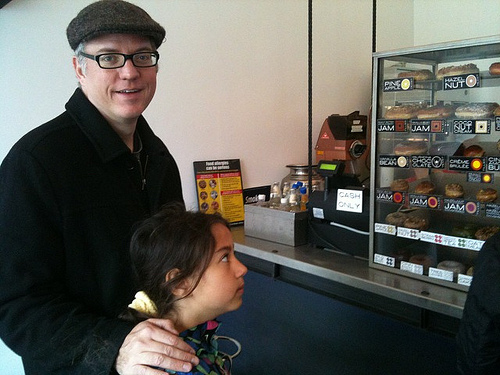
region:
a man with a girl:
[2, 2, 199, 373]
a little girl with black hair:
[120, 210, 247, 373]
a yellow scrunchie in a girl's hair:
[125, 285, 160, 318]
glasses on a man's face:
[80, 45, 160, 70]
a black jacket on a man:
[0, 85, 182, 371]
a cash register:
[307, 155, 368, 255]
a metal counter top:
[205, 215, 495, 365]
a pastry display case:
[362, 30, 492, 280]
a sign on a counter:
[187, 155, 253, 226]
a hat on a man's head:
[63, 1, 169, 46]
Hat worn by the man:
[63, 0, 170, 50]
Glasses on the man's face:
[75, 45, 162, 72]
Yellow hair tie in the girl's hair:
[122, 286, 158, 320]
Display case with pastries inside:
[361, 23, 498, 293]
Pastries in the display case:
[384, 58, 498, 283]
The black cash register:
[301, 148, 373, 265]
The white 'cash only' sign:
[332, 182, 367, 216]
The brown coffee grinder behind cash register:
[309, 106, 368, 173]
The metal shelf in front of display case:
[228, 220, 469, 317]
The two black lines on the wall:
[302, 0, 381, 199]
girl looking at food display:
[120, 210, 282, 374]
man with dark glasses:
[65, 0, 166, 125]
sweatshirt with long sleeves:
[0, 84, 220, 373]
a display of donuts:
[364, 35, 497, 305]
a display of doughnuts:
[354, 39, 498, 299]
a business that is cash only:
[329, 184, 366, 216]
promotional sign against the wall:
[190, 150, 251, 239]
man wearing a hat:
[55, 0, 177, 128]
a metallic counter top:
[281, 237, 478, 312]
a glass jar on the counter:
[273, 155, 329, 212]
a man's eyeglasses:
[73, 48, 160, 68]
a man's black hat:
[59, 0, 169, 47]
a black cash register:
[307, 158, 374, 256]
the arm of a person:
[452, 227, 498, 374]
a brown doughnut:
[442, 179, 463, 199]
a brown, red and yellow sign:
[192, 159, 246, 230]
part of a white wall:
[311, 0, 374, 168]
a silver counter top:
[225, 222, 467, 312]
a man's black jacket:
[0, 88, 187, 373]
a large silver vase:
[281, 160, 323, 197]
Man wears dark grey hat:
[63, 7, 163, 33]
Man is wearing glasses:
[88, 51, 165, 66]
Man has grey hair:
[66, 48, 91, 64]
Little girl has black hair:
[143, 222, 196, 267]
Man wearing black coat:
[24, 175, 79, 228]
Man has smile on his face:
[48, 4, 191, 119]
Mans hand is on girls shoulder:
[96, 315, 215, 372]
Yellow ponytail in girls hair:
[123, 290, 163, 317]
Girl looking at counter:
[128, 205, 270, 329]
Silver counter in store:
[287, 246, 358, 286]